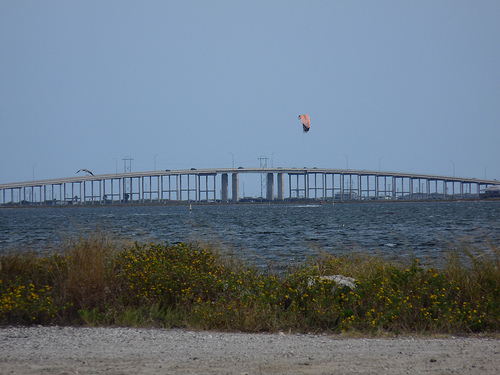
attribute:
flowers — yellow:
[107, 246, 304, 292]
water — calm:
[338, 210, 466, 249]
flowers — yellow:
[118, 238, 219, 310]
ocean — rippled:
[3, 205, 498, 260]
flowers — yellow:
[335, 265, 454, 310]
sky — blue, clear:
[1, 1, 499, 198]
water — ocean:
[2, 200, 499, 270]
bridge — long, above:
[1, 165, 498, 198]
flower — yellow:
[17, 285, 24, 292]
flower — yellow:
[30, 290, 40, 300]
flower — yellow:
[9, 297, 13, 303]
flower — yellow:
[40, 291, 47, 298]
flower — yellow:
[18, 283, 25, 292]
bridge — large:
[137, 151, 342, 200]